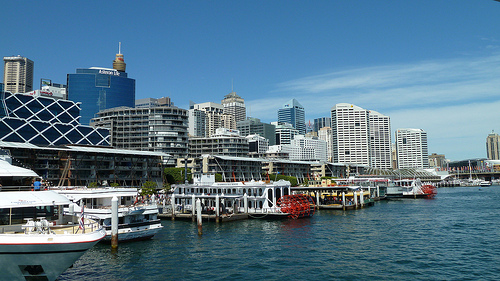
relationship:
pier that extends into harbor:
[296, 182, 362, 210] [62, 180, 499, 279]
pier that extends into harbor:
[158, 205, 248, 222] [62, 180, 499, 279]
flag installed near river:
[432, 163, 499, 176] [123, 185, 499, 271]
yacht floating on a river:
[167, 175, 297, 230] [69, 182, 495, 277]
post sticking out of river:
[100, 192, 121, 252] [309, 216, 494, 277]